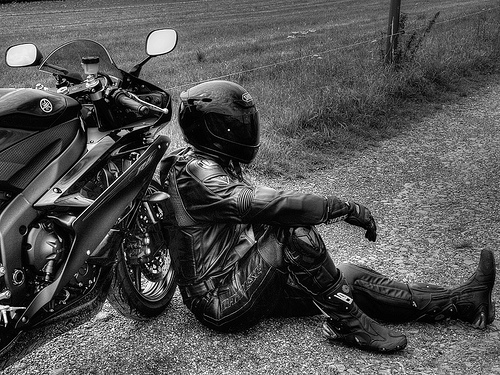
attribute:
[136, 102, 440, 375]
motorcyclist — resting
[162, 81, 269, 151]
helmet — black, shiny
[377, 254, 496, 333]
boot — black, long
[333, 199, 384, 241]
glove — black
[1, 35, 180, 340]
motorcycle — black, parked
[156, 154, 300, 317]
jacket — leather, metal, black, thick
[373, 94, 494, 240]
road — gravel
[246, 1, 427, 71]
fence — wooden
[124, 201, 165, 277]
rim — chrome